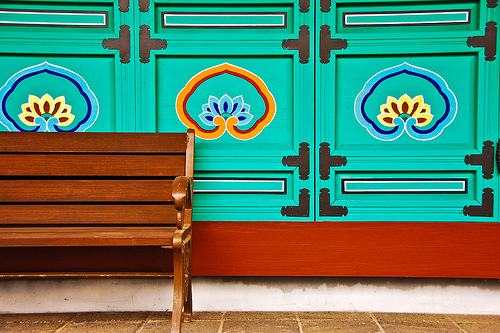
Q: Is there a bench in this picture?
A: Yes, there is a bench.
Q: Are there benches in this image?
A: Yes, there is a bench.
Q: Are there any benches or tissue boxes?
A: Yes, there is a bench.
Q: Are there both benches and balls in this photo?
A: No, there is a bench but no balls.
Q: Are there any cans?
A: No, there are no cans.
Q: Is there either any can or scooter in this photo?
A: No, there are no cans or scooters.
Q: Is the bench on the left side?
A: Yes, the bench is on the left of the image.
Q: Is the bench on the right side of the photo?
A: No, the bench is on the left of the image.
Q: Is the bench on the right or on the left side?
A: The bench is on the left of the image.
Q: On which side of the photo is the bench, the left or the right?
A: The bench is on the left of the image.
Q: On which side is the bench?
A: The bench is on the left of the image.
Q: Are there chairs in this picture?
A: No, there are no chairs.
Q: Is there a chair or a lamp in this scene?
A: No, there are no chairs or lamps.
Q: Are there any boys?
A: No, there are no boys.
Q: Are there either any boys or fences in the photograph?
A: No, there are no boys or fences.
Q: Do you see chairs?
A: No, there are no chairs.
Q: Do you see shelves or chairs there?
A: No, there are no chairs or shelves.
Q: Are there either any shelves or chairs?
A: No, there are no chairs or shelves.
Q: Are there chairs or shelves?
A: No, there are no chairs or shelves.